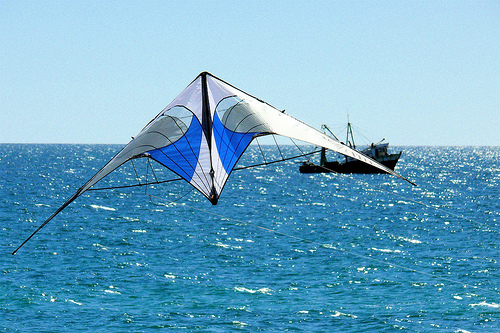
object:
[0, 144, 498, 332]
ocean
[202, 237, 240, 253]
ripples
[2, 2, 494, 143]
sky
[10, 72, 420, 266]
kite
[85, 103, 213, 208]
stripe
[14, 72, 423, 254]
spreader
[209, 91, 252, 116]
section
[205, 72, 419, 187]
edge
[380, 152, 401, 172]
front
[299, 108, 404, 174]
boat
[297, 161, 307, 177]
back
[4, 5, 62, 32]
section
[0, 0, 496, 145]
background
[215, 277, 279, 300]
waves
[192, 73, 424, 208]
triangles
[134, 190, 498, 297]
strings